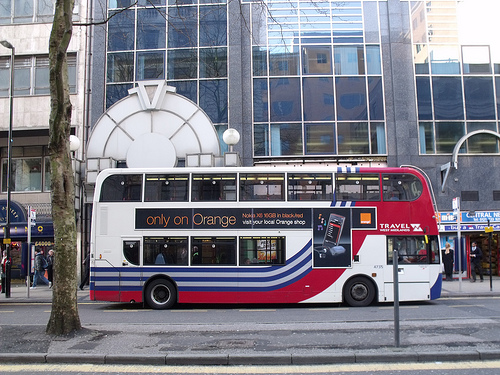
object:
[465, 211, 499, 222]
lettering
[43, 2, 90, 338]
tree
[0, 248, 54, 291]
people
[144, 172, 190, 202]
window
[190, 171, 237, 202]
window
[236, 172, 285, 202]
window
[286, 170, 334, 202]
window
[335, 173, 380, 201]
window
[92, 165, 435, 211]
upper level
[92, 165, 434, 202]
level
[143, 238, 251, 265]
passengers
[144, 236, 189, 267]
window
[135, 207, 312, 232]
advertisement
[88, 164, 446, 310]
bus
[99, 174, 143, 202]
windows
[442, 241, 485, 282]
pedestrians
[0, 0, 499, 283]
building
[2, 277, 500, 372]
street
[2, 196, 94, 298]
background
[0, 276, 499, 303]
sidewalk